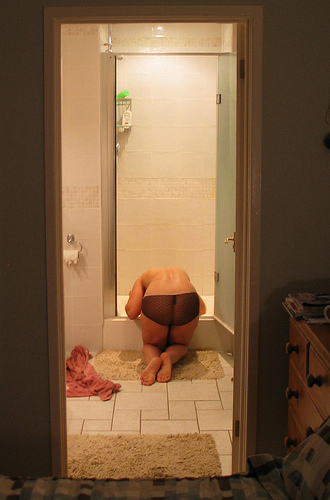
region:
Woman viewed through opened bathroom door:
[47, 51, 250, 476]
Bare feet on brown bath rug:
[89, 352, 225, 386]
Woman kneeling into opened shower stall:
[122, 265, 209, 387]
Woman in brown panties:
[140, 290, 202, 327]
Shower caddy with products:
[115, 88, 132, 133]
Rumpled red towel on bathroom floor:
[64, 338, 122, 402]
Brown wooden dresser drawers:
[280, 320, 328, 453]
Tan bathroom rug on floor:
[65, 430, 223, 477]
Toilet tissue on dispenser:
[64, 234, 83, 266]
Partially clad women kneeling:
[118, 258, 210, 387]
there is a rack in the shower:
[107, 75, 136, 153]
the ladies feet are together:
[129, 326, 185, 388]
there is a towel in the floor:
[64, 317, 121, 412]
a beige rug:
[64, 417, 227, 488]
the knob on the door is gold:
[210, 213, 248, 259]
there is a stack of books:
[266, 268, 328, 337]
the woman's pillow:
[240, 427, 328, 498]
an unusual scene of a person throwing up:
[38, 127, 269, 387]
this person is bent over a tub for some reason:
[115, 260, 227, 400]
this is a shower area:
[81, 35, 226, 268]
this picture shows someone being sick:
[99, 152, 238, 399]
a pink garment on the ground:
[62, 333, 121, 406]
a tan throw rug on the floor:
[67, 422, 216, 477]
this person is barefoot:
[124, 344, 190, 383]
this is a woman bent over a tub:
[99, 249, 231, 405]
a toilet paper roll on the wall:
[63, 223, 90, 264]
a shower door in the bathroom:
[201, 187, 240, 348]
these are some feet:
[136, 364, 178, 382]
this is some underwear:
[144, 309, 184, 331]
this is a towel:
[90, 365, 102, 380]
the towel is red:
[68, 366, 99, 402]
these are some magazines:
[269, 289, 293, 320]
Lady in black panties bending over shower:
[119, 260, 210, 388]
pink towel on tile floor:
[68, 337, 121, 404]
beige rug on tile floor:
[63, 430, 225, 474]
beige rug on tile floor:
[191, 344, 224, 381]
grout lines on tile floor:
[160, 395, 176, 425]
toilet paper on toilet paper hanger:
[62, 246, 80, 268]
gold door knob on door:
[225, 225, 239, 255]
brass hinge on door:
[237, 54, 247, 83]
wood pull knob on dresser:
[284, 339, 300, 362]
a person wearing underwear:
[128, 259, 220, 352]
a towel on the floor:
[70, 341, 133, 400]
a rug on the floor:
[92, 340, 254, 394]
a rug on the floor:
[67, 424, 223, 483]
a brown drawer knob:
[286, 338, 302, 359]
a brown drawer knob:
[302, 360, 324, 385]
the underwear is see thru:
[139, 293, 200, 343]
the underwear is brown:
[139, 306, 203, 335]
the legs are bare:
[124, 317, 205, 377]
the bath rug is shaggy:
[90, 422, 179, 457]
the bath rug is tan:
[97, 429, 179, 498]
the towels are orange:
[73, 350, 110, 390]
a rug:
[87, 436, 198, 479]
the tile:
[156, 394, 197, 422]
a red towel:
[71, 365, 103, 394]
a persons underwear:
[148, 300, 197, 321]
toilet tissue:
[65, 248, 79, 263]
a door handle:
[221, 230, 238, 248]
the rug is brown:
[77, 439, 179, 473]